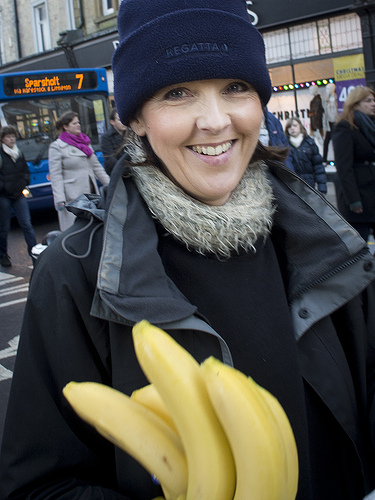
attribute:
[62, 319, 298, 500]
banana — yellow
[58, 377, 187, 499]
banana — yellow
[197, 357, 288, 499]
banana — yellow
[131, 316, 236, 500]
banana — yellow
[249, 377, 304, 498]
banana — yellow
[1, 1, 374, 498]
woman — smiling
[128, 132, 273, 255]
scarf — furry, gray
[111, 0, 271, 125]
cap — blue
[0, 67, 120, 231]
bus — blue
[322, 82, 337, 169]
mannequin — white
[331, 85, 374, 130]
hair — brown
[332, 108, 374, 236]
coat — black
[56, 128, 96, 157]
scarf — purple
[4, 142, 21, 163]
scarf — white